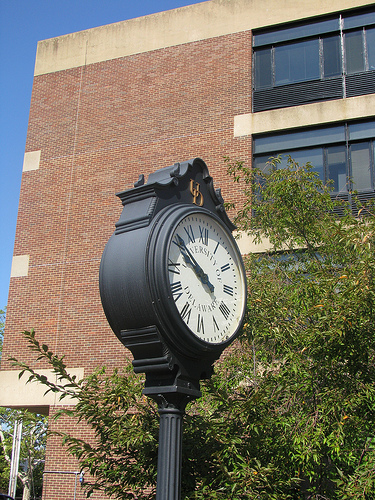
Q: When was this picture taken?
A: Daytime.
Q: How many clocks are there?
A: One clock.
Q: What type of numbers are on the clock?
A: Roman numerals.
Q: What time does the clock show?
A: 9:51.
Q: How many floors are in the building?
A: Four floors.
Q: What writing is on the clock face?
A: University of Delaware.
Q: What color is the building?
A: Brown and beige.